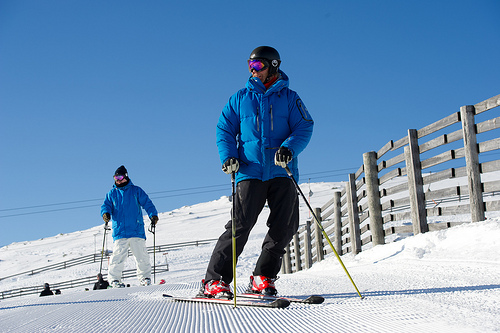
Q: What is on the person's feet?
A: Skis.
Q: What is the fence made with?
A: Wood.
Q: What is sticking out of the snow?
A: A fence.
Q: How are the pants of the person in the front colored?
A: Black.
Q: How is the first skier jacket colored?
A: Blue.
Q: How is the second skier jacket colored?
A: Blue.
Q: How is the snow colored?
A: White.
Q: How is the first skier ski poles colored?
A: Yellow and black.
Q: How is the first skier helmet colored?
A: Black.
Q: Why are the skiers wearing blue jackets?
A: It is cold where they are.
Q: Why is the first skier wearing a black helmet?
A: For protection.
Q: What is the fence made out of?
A: Wood.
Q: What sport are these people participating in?
A: Skiing.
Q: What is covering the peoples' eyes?
A: Goggles.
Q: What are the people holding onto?
A: Ski poles.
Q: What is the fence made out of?
A: Wood.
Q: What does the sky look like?
A: Blue and clear.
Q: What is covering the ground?
A: Snow.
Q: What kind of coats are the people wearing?
A: Down jackets.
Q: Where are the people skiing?
A: On a mountain.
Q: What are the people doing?
A: Skiing.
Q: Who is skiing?
A: People.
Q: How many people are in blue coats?
A: Two.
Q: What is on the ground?
A: Snow.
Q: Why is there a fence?
A: Safety.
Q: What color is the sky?
A: Blue.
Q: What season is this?
A: Winter.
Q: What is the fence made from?
A: Wood.